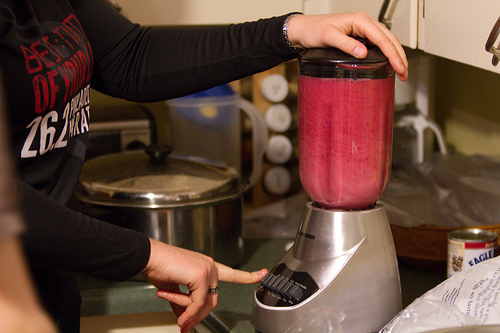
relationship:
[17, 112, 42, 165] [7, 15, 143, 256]
white lettering have shirt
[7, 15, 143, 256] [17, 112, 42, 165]
shirt have white lettering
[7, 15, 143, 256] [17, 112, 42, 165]
shirt has white lettering